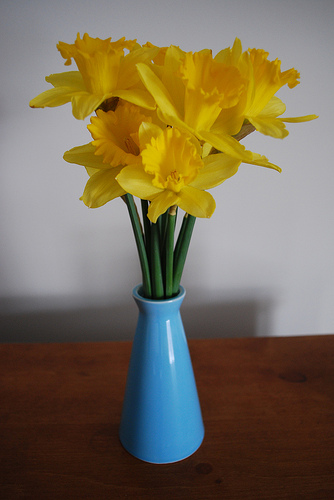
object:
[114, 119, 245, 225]
flowers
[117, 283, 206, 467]
vase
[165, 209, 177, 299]
stems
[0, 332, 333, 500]
table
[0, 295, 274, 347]
shadow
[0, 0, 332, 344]
wall